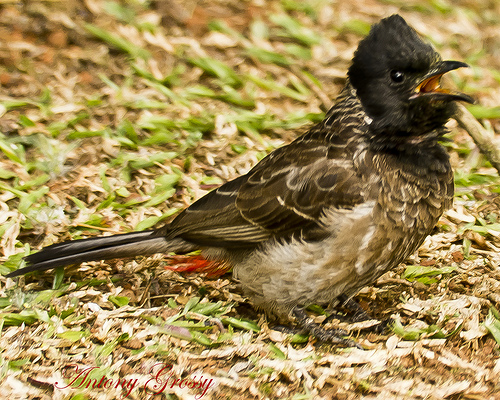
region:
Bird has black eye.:
[388, 64, 412, 96]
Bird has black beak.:
[435, 48, 470, 150]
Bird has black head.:
[357, 35, 406, 53]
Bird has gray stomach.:
[310, 262, 372, 301]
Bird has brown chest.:
[398, 168, 455, 265]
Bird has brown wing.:
[248, 177, 305, 236]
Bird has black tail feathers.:
[43, 215, 140, 335]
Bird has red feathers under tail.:
[189, 255, 255, 290]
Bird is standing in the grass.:
[255, 260, 387, 337]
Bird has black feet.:
[308, 294, 344, 356]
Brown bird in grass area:
[36, 16, 498, 318]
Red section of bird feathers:
[147, 237, 245, 307]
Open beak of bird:
[405, 54, 470, 156]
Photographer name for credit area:
[31, 355, 222, 396]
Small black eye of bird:
[383, 64, 410, 93]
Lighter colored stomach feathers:
[232, 202, 415, 308]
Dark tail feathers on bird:
[0, 217, 174, 264]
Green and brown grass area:
[3, 26, 217, 179]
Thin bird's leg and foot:
[286, 307, 364, 365]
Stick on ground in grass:
[456, 89, 495, 177]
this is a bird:
[34, 18, 486, 330]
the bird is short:
[16, 15, 487, 336]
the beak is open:
[425, 54, 474, 105]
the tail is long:
[17, 210, 174, 268]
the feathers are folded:
[234, 152, 328, 232]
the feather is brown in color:
[247, 151, 337, 216]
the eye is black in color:
[390, 69, 410, 84]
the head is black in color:
[365, 24, 410, 62]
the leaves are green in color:
[106, 38, 251, 131]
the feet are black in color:
[307, 305, 372, 347]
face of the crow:
[346, 12, 496, 147]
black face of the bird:
[350, 26, 465, 162]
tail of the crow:
[42, 198, 187, 311]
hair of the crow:
[186, 166, 345, 246]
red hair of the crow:
[160, 249, 222, 291]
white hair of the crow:
[263, 239, 372, 301]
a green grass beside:
[25, 22, 477, 327]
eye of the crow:
[382, 64, 409, 87]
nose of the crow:
[418, 59, 484, 128]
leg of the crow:
[294, 313, 363, 362]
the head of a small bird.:
[337, 19, 495, 181]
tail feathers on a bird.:
[0, 179, 248, 289]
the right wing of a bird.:
[23, 146, 424, 326]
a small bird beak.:
[403, 36, 484, 153]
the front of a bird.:
[224, 193, 432, 323]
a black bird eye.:
[370, 46, 429, 98]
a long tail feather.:
[0, 174, 229, 312]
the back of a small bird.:
[173, 70, 377, 231]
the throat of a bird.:
[375, 110, 454, 162]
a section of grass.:
[438, 251, 484, 300]